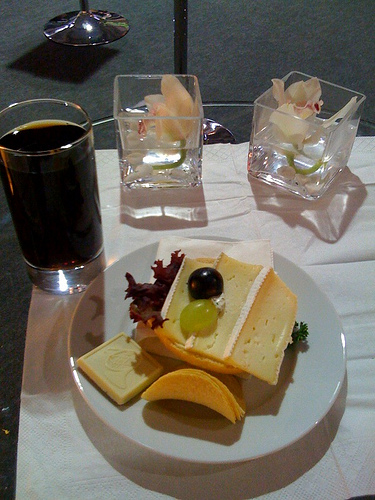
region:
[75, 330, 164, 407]
white chocolate square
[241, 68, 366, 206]
square glass with a white orchid in it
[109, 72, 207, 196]
square glass with a white orchid in it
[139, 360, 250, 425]
small stack of pringles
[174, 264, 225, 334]
two grapes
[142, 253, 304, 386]
sliced cheese with two grapes on top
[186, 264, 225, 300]
dark purple grape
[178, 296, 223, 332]
pale green grape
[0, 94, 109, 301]
round glass containng a dark drink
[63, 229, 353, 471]
white ceramic plate full of food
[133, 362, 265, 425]
chips on plate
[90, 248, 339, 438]
plate of food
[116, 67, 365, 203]
decorations for table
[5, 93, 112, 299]
glass of soda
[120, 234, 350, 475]
white plate with food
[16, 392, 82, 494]
placemat on table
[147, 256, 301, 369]
sandwich with cheese and grapes on plate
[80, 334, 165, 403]
after dinner mint on plate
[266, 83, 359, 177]
white flower in square glass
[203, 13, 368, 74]
table top is grey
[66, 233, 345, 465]
artistic snack plate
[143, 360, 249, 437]
pringles potato chips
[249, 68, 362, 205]
square glass with floating flower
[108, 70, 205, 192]
square glass with floating flower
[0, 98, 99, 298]
glass of soda without ice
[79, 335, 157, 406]
square of white chocolate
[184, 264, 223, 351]
grapes cut in half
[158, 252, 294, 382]
3 cheese slices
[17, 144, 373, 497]
white napkin unfolded under place setting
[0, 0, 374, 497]
glass topped dining table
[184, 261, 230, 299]
red grape on a sandwhich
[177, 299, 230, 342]
green grape on a sandwhich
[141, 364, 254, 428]
5 pringles chips on a plate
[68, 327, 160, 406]
a square piece of white chocolate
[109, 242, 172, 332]
Red lettuce under cheese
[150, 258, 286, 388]
three slices of cheese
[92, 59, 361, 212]
Two glasses with flowers in them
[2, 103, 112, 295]
tall drinking glass with dark liquid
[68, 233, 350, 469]
white plate with food on it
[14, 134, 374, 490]
white napkin placed under the plate and glasses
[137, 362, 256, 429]
chips on a plate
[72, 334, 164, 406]
a cookie on the plate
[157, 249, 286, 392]
cheese on the plate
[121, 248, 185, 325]
red lettuce by the cheese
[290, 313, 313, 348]
green parsley under the cheese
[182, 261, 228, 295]
a red grape on the cheese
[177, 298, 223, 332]
a green grape on the cheese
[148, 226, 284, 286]
a napkin on the plate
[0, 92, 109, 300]
a glass beside the plate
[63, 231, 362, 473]
the plate is white and round